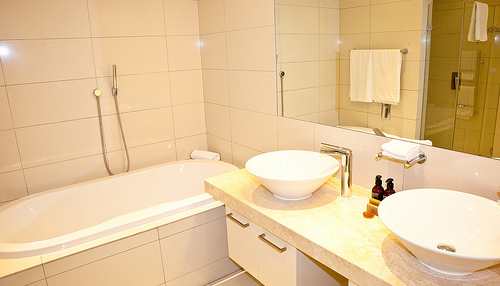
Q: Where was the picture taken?
A: In a bathroom.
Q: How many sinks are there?
A: Two.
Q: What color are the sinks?
A: White.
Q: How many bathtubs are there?
A: One.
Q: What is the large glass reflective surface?
A: A mirror.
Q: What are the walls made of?
A: Tile.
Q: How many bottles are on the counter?
A: Two.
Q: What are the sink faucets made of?
A: Metal.